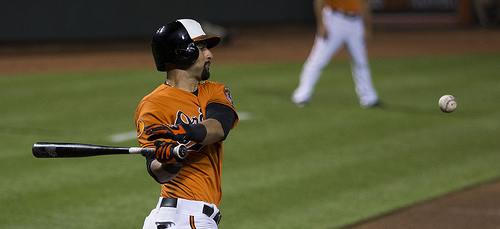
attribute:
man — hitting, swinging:
[135, 19, 236, 228]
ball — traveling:
[437, 93, 461, 115]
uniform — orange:
[137, 81, 237, 204]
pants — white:
[143, 194, 222, 227]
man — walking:
[295, 3, 389, 110]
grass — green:
[6, 64, 488, 205]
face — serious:
[189, 41, 215, 84]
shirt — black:
[138, 81, 237, 205]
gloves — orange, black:
[149, 122, 195, 164]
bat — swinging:
[33, 139, 189, 161]